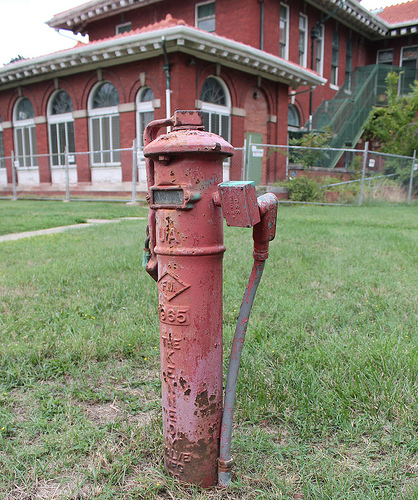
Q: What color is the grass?
A: Green.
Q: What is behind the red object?
A: A fence.